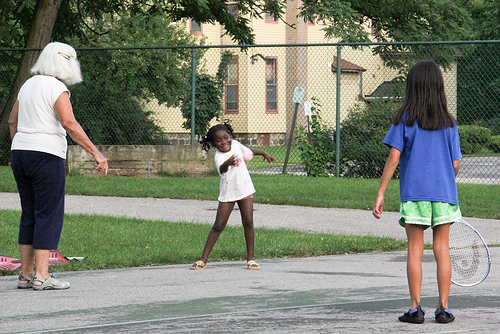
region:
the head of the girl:
[199, 118, 244, 155]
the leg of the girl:
[236, 191, 258, 258]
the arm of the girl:
[236, 140, 265, 162]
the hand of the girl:
[224, 151, 241, 169]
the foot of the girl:
[186, 253, 215, 272]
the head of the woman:
[29, 35, 87, 88]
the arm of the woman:
[46, 76, 96, 155]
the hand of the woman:
[86, 150, 113, 180]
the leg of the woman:
[30, 153, 75, 274]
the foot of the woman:
[26, 267, 74, 295]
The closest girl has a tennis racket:
[364, 51, 492, 326]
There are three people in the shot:
[9, 36, 460, 323]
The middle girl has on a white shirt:
[192, 118, 274, 272]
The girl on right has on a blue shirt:
[375, 96, 461, 205]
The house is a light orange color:
[81, 16, 455, 135]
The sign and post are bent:
[278, 84, 307, 175]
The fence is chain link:
[2, 40, 498, 186]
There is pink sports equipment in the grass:
[0, 246, 76, 273]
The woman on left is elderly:
[7, 42, 109, 289]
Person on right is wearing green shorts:
[396, 196, 457, 232]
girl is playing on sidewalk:
[199, 106, 261, 260]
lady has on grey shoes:
[20, 272, 80, 308]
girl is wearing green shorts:
[410, 209, 467, 234]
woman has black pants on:
[8, 145, 59, 253]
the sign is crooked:
[277, 85, 310, 192]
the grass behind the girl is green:
[255, 175, 373, 206]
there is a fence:
[250, 87, 380, 173]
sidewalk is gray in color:
[73, 272, 369, 332]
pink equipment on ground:
[0, 251, 17, 267]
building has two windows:
[225, 86, 276, 122]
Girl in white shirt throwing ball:
[193, 125, 275, 272]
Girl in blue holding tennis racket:
[372, 62, 492, 322]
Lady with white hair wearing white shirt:
[12, 37, 109, 287]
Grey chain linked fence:
[246, 34, 385, 183]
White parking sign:
[278, 82, 309, 174]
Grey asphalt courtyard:
[2, 241, 488, 332]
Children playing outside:
[192, 56, 492, 323]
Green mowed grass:
[73, 211, 195, 268]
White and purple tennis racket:
[438, 213, 492, 287]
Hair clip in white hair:
[29, 40, 83, 86]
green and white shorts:
[393, 195, 464, 225]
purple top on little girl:
[380, 111, 461, 201]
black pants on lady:
[5, 145, 70, 250]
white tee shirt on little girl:
[201, 135, 256, 200]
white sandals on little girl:
[186, 258, 262, 273]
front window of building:
[252, 50, 280, 115]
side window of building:
[215, 47, 246, 117]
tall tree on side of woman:
[1, 2, 281, 142]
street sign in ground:
[278, 83, 304, 170]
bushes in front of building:
[302, 108, 492, 177]